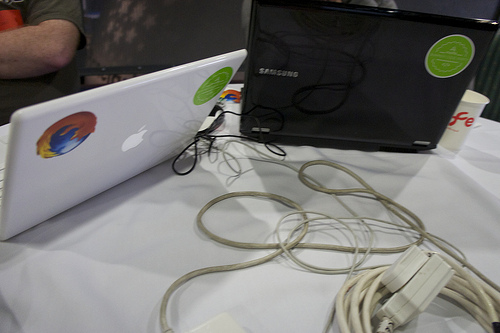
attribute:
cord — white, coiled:
[357, 244, 455, 328]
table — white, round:
[104, 229, 161, 258]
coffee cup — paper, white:
[451, 77, 482, 162]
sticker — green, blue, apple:
[410, 35, 470, 87]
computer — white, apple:
[258, 12, 432, 148]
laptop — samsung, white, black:
[14, 68, 197, 218]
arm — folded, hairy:
[1, 19, 76, 81]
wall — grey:
[186, 21, 232, 52]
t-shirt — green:
[0, 78, 58, 91]